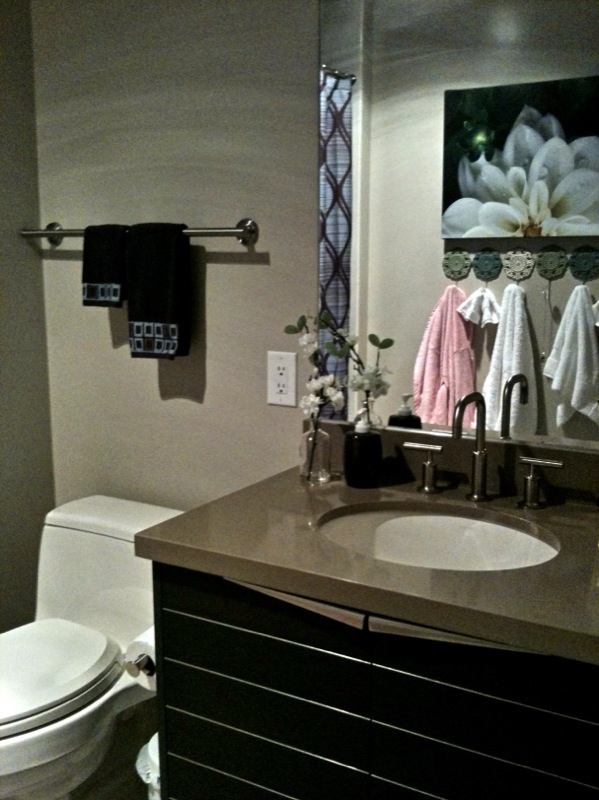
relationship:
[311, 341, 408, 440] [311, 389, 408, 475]
flower inside a vase